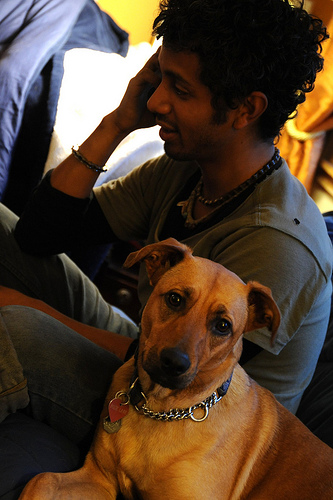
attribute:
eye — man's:
[169, 80, 189, 99]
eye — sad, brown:
[166, 290, 184, 306]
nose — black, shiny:
[39, 240, 332, 498]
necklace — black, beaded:
[188, 144, 287, 212]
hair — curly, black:
[148, 3, 331, 102]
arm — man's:
[24, 44, 159, 262]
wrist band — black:
[68, 143, 114, 175]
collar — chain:
[102, 343, 231, 433]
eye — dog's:
[210, 313, 243, 349]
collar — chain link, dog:
[97, 355, 236, 440]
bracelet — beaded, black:
[68, 145, 107, 174]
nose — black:
[159, 350, 203, 368]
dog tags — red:
[100, 397, 128, 433]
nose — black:
[159, 348, 190, 376]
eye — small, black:
[165, 287, 184, 309]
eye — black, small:
[213, 317, 232, 336]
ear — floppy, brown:
[240, 278, 288, 346]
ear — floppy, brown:
[111, 230, 194, 284]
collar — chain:
[127, 353, 234, 423]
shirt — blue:
[14, 137, 330, 420]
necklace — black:
[161, 150, 286, 221]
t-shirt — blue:
[92, 148, 332, 418]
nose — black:
[146, 342, 204, 379]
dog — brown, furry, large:
[17, 228, 332, 499]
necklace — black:
[190, 151, 280, 206]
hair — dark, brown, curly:
[233, 26, 298, 78]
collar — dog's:
[111, 334, 237, 421]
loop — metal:
[187, 402, 209, 421]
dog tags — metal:
[103, 397, 130, 433]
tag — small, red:
[100, 397, 129, 433]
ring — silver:
[187, 400, 208, 422]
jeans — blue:
[1, 201, 140, 449]